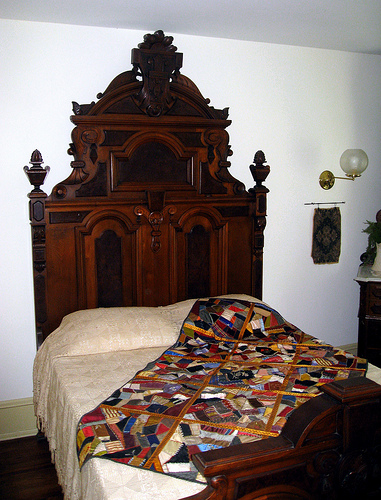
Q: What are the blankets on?
A: A bed.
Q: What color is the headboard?
A: Brown.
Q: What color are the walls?
A: White.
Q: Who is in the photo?
A: Nobody.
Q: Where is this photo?
A: In a bedroom.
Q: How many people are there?
A: None.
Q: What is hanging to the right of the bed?
A: A light and a towel.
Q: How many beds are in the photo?
A: One.